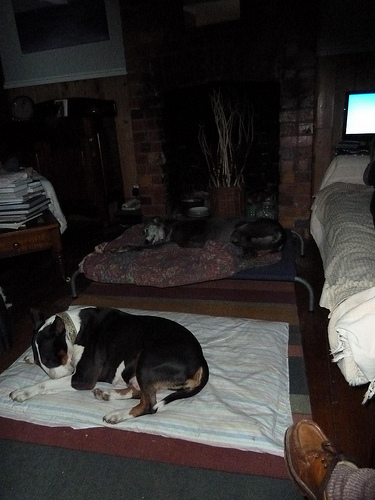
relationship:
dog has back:
[9, 304, 209, 424] [121, 311, 199, 345]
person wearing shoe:
[281, 417, 374, 494] [281, 417, 345, 492]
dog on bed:
[9, 304, 209, 424] [0, 278, 313, 499]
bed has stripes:
[0, 304, 294, 456] [3, 303, 294, 459]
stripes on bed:
[3, 303, 294, 459] [0, 304, 294, 456]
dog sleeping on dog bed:
[100, 212, 295, 259] [81, 219, 283, 288]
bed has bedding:
[309, 157, 373, 403] [310, 181, 373, 402]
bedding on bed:
[310, 181, 373, 402] [309, 157, 373, 403]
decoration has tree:
[196, 87, 249, 217] [199, 93, 254, 187]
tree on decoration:
[199, 93, 254, 187] [196, 87, 249, 217]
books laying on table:
[0, 167, 52, 229] [0, 211, 69, 290]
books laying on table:
[0, 176, 52, 229] [0, 209, 68, 295]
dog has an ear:
[11, 303, 217, 420] [48, 309, 68, 333]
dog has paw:
[11, 303, 217, 420] [12, 381, 33, 400]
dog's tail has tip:
[150, 357, 213, 411] [149, 396, 168, 414]